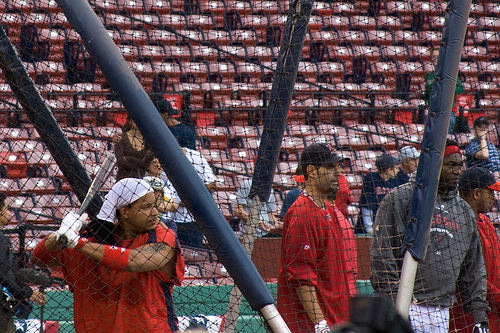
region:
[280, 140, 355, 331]
A man in a red shirt with sleeves rolled up and black hat.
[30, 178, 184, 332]
A colored man holding a bat with a white cloth on his head.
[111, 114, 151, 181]
A woman in a brown shirt with her arms folded.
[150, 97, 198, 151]
A man with a backwards hat holding onto a woman in a brown shirt.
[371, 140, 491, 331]
A large colored man in grey sweatshirt and red headband.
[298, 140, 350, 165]
Black hat on a man with rolled up sleeves on his red shirt.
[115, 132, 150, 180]
Brown shirt on a woman standing in the stands.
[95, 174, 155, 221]
White rag on a colored man's head.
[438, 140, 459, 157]
Red headband in a black man's hair.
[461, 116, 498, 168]
Guy in a black hat sitting in the stands with a blue and white checkered shirt on.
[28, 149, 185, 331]
man standing in batting cage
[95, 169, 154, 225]
white doorag on man's head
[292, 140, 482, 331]
two men standing beside batting cage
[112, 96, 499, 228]
people watching batting practice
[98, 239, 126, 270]
red armband of baseball player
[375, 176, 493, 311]
gray sweatshirt player is wearing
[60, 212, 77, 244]
white batting gloves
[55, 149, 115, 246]
black bat batter is holding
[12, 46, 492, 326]
black netting around batting cage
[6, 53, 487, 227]
empty seats in the stands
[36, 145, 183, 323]
man wearing white head wrap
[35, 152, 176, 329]
man holding a bat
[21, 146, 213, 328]
man weaing red shirt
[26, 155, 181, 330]
man wearing arm band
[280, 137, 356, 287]
man wearing a cap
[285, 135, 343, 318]
man wearing red shirt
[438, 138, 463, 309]
man wearing head band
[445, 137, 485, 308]
man wearing gray shirt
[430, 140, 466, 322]
man wearing white pants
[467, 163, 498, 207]
man wearing a cap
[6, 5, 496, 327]
Baseball players taking batting practice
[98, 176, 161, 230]
Guy wearing white bandana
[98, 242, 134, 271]
Red and white armband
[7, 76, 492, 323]
Metal and rubber batting cage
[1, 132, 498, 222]
Spectators sitting in stands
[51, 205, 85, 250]
White batting gloves holding bat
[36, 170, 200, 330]
Player with cocked bat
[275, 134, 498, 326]
Other players awaiting turn in cage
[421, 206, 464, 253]
Boston Red sox logo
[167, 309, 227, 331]
US flag bunting draping fence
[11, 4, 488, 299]
a professional baseball team at practice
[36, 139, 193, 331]
a playing practicing batting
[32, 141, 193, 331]
a player holding baseball bat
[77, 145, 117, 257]
a black wooden baseball bat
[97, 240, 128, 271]
a read and white writing band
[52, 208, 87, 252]
white hitting gloves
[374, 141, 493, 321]
a man with a gray jacket on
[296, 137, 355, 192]
a man wearing a black cap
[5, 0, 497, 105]
the spectator seats in a baseball stadium